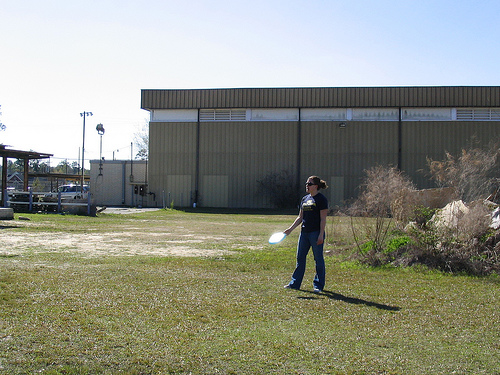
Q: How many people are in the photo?
A: One.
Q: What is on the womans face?
A: Sunglasses.